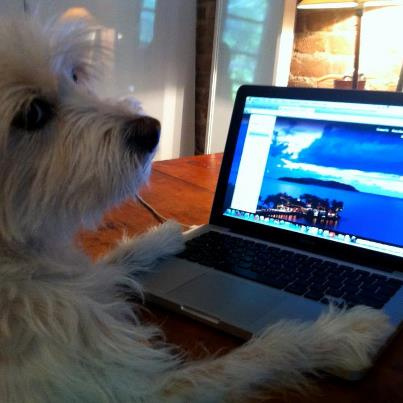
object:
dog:
[0, 13, 393, 403]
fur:
[26, 144, 90, 210]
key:
[203, 239, 261, 265]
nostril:
[126, 131, 152, 154]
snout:
[111, 109, 163, 172]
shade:
[291, 2, 399, 12]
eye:
[16, 97, 49, 130]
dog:
[2, 20, 387, 400]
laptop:
[120, 85, 402, 353]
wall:
[14, 1, 195, 170]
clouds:
[276, 118, 402, 196]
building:
[259, 7, 401, 83]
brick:
[292, 27, 331, 51]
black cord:
[134, 190, 187, 227]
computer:
[111, 82, 401, 372]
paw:
[121, 216, 190, 268]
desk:
[164, 138, 207, 198]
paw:
[309, 301, 393, 372]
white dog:
[0, 12, 388, 402]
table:
[153, 162, 207, 219]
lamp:
[293, 0, 401, 86]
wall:
[278, 1, 401, 100]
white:
[281, 300, 396, 371]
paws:
[75, 218, 390, 364]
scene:
[207, 84, 401, 235]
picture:
[252, 118, 403, 246]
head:
[0, 0, 161, 243]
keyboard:
[171, 227, 402, 310]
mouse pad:
[162, 268, 288, 328]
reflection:
[47, 5, 118, 79]